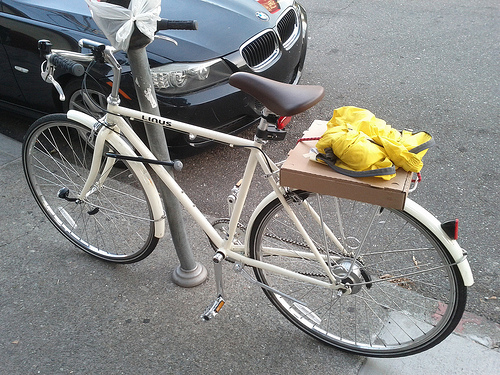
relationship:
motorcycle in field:
[8, 36, 472, 367] [8, 141, 468, 371]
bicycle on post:
[41, 17, 484, 353] [21, 158, 490, 370]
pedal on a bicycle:
[183, 284, 251, 343] [41, 17, 484, 353]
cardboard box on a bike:
[265, 101, 441, 230] [38, 2, 479, 357]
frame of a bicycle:
[104, 100, 275, 288] [41, 17, 484, 353]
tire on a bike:
[15, 97, 158, 290] [38, 2, 479, 357]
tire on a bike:
[207, 163, 476, 360] [38, 2, 479, 357]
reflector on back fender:
[439, 214, 480, 248] [405, 201, 474, 326]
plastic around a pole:
[80, 7, 167, 53] [96, 0, 179, 165]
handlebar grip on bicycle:
[5, 40, 85, 110] [33, 4, 495, 371]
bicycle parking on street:
[34, 0, 482, 351] [17, 2, 498, 340]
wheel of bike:
[232, 170, 488, 373] [24, 1, 499, 345]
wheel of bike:
[24, 110, 177, 285] [38, 2, 479, 357]